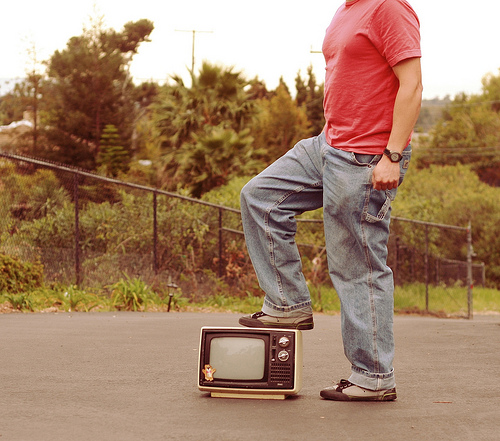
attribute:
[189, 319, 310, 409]
tv — old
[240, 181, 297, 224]
knee — bent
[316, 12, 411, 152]
shirt — red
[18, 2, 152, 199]
pine trees — dark green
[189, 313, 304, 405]
screen — small, grey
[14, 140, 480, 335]
fence — black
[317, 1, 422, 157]
shirt — red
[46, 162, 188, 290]
fence — black, chain-link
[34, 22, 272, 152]
trees — green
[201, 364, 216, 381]
bear — small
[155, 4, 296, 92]
cloudy — white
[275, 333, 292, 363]
knobs — small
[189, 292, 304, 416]
tv — small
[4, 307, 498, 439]
concrete — grey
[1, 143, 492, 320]
fence — black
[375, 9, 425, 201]
arm — mans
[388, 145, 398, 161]
watch — black